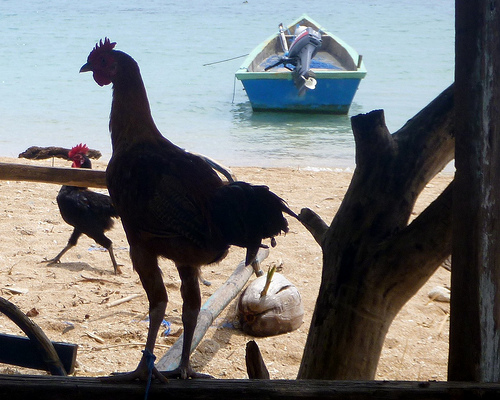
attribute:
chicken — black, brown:
[68, 37, 313, 381]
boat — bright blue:
[252, 19, 359, 103]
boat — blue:
[223, 6, 380, 126]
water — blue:
[2, 2, 457, 174]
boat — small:
[224, 15, 359, 120]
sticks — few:
[77, 272, 143, 330]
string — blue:
[139, 349, 157, 397]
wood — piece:
[10, 367, 497, 397]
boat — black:
[236, 13, 366, 116]